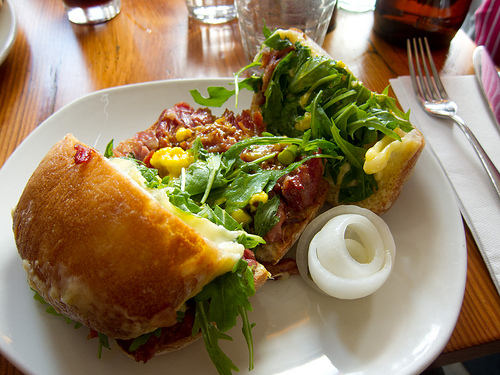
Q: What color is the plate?
A: White.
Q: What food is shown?
A: Sandwich.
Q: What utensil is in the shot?
A: Fork.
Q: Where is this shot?
A: Table.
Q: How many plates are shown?
A: 1.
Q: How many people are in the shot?
A: 0.